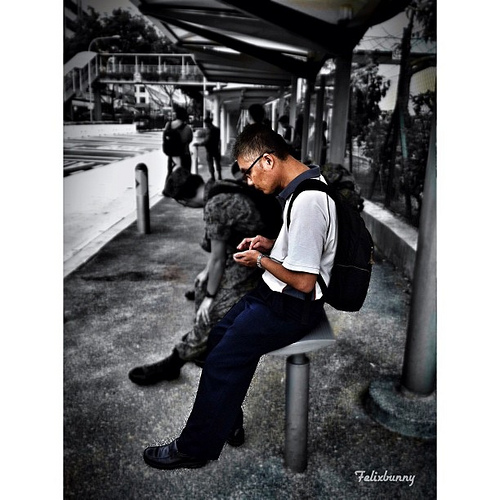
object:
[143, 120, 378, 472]
man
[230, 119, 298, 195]
head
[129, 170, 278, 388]
soldier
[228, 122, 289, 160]
hair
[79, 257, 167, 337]
grass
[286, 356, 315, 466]
pole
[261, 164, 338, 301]
shirt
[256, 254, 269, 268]
watch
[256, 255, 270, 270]
wrist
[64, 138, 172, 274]
sidewalk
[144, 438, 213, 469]
foot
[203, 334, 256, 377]
knee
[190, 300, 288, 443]
leg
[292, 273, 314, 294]
elbow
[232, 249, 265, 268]
hand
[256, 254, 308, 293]
arm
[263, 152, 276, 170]
ear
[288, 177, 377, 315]
backpack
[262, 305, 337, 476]
bench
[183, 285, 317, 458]
jean